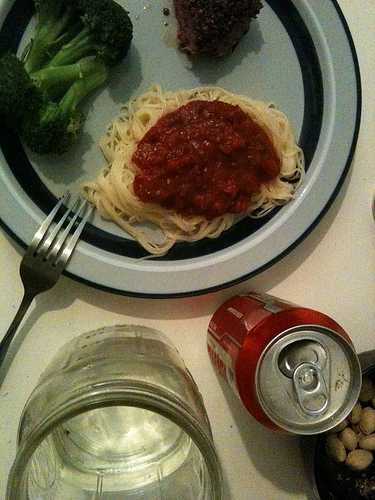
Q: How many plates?
A: One.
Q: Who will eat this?
A: Man.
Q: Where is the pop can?
A: Below the plate.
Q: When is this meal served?
A: Dinner.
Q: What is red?
A: Sauce.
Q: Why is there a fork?
A: To eat with.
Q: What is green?
A: Broccoli.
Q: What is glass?
A: The jar.